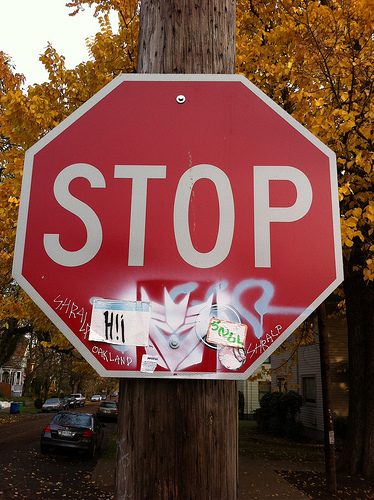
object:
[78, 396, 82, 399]
white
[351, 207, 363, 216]
leaves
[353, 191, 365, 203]
leaves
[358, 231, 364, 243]
leaves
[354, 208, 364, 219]
leaves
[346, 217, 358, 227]
leaves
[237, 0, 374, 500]
trees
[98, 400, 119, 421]
car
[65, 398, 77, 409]
car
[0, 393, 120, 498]
street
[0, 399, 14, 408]
fence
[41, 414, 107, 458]
black car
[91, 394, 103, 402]
car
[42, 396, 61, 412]
car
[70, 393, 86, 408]
car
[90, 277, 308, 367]
graffiti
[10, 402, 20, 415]
container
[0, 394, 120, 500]
road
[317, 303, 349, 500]
pole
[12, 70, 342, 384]
sign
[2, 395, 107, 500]
street